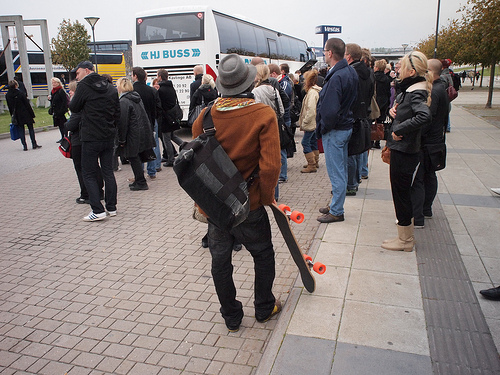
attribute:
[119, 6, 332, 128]
bus — white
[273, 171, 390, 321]
wheels — orange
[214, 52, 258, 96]
cap — grey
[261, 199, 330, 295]
skateboard — vertical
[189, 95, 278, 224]
coat — brown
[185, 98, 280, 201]
sweater — brown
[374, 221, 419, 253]
boots — tan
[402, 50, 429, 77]
hair — blonde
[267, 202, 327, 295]
skateboard — black, orange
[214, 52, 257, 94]
hat — gray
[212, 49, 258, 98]
hat — grey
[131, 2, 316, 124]
bus — white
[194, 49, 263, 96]
hat — gray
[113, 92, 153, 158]
jacket — hooded